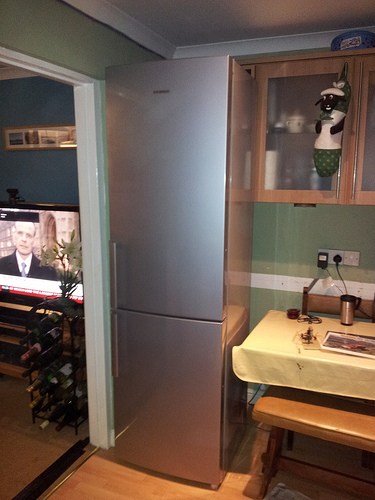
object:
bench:
[249, 376, 374, 499]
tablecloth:
[230, 305, 373, 402]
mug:
[337, 294, 355, 327]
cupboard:
[249, 48, 375, 211]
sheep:
[312, 77, 352, 115]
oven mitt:
[314, 65, 354, 177]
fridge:
[99, 53, 260, 488]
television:
[0, 202, 98, 319]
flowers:
[37, 225, 87, 301]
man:
[0, 218, 54, 287]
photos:
[2, 123, 78, 151]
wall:
[0, 72, 79, 209]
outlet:
[318, 244, 361, 268]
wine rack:
[16, 294, 90, 439]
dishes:
[284, 111, 303, 133]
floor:
[0, 373, 267, 498]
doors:
[98, 46, 232, 494]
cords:
[312, 252, 329, 278]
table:
[229, 304, 374, 499]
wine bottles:
[17, 325, 67, 367]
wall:
[251, 199, 374, 322]